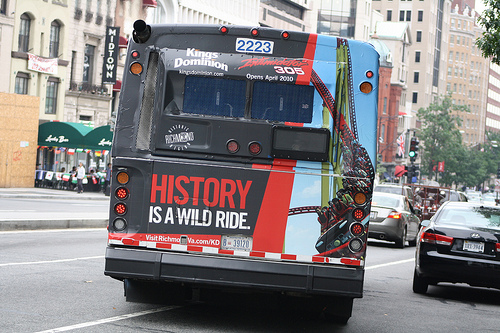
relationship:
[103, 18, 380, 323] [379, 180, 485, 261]
bus pulling into traffic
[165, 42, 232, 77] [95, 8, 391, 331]
logo on car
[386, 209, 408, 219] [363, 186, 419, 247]
tail light on car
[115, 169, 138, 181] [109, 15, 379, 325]
reflector on bus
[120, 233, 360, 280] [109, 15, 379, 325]
reflector strip on bus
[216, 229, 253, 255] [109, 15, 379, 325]
license plate on bus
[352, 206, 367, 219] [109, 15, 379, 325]
brake light on bus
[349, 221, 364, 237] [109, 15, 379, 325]
brake light on bus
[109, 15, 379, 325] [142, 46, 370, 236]
bus has advertisement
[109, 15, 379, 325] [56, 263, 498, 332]
bus on road side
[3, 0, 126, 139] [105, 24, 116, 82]
building has sign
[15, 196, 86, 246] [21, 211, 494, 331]
median in road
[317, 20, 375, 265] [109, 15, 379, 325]
roller coaster on bus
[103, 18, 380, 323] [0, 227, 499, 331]
bus on road